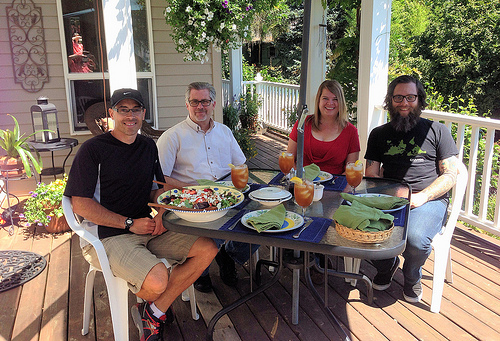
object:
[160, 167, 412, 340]
table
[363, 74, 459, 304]
man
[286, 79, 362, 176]
woman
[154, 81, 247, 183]
gentleman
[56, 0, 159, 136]
window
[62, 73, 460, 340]
people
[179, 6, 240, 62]
plant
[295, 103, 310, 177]
pole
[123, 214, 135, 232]
watch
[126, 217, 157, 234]
hand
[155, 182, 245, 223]
bowl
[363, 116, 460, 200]
shirt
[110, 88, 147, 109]
cap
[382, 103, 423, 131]
beard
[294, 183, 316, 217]
glass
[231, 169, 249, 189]
drink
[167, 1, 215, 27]
flowers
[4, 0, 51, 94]
artwork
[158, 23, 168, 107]
wall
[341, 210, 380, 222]
napkin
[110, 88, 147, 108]
hat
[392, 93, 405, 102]
glasses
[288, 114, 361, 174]
shirt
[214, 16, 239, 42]
flower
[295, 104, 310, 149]
crank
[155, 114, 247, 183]
shirt